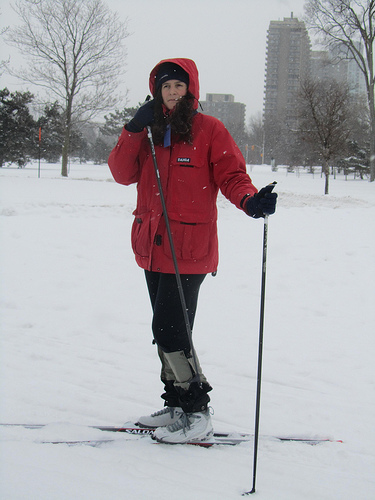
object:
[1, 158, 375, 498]
snow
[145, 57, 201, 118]
hood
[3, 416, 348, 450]
skis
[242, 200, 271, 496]
ski pole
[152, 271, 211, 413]
crossed legs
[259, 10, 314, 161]
building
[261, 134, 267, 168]
traffic light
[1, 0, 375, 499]
background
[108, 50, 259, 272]
ski jacket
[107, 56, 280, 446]
lady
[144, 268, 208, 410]
black pants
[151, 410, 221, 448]
ski boot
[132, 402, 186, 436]
ski boot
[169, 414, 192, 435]
laces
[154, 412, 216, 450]
shoe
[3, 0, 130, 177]
tree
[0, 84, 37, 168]
tree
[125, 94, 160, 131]
gloves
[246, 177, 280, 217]
gloves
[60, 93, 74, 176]
trunk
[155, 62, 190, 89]
hat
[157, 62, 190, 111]
head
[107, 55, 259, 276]
coat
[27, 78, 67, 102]
branch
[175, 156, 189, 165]
label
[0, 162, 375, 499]
field